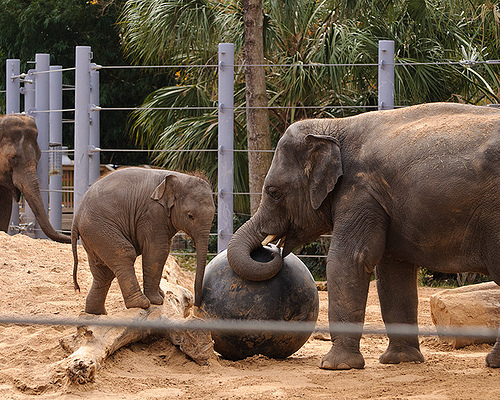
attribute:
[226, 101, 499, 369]
elephant — big, standing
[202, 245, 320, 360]
ball — large, giant, black, dirty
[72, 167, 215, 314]
elephant — a baby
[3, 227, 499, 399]
dirt — sandy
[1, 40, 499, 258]
fence — metal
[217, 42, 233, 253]
post — metal